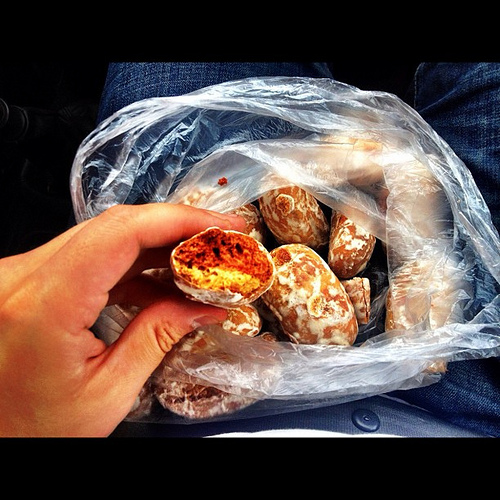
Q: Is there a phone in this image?
A: No, there are no phones.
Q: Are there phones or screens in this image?
A: No, there are no phones or screens.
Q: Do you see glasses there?
A: No, there are no glasses.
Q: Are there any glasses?
A: No, there are no glasses.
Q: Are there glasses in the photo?
A: No, there are no glasses.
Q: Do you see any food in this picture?
A: Yes, there is food.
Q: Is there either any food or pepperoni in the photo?
A: Yes, there is food.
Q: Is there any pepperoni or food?
A: Yes, there is food.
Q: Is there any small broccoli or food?
A: Yes, there is small food.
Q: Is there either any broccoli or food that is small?
A: Yes, the food is small.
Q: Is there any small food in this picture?
A: Yes, there is small food.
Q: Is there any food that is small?
A: Yes, there is food that is small.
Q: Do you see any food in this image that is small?
A: Yes, there is food that is small.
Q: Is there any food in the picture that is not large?
A: Yes, there is small food.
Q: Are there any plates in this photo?
A: No, there are no plates.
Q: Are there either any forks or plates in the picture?
A: No, there are no plates or forks.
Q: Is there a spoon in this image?
A: No, there are no spoons.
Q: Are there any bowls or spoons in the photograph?
A: No, there are no spoons or bowls.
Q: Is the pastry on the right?
A: Yes, the pastry is on the right of the image.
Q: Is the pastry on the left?
A: No, the pastry is on the right of the image.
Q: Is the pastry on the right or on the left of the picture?
A: The pastry is on the right of the image.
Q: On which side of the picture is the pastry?
A: The pastry is on the right of the image.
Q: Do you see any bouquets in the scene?
A: No, there are no bouquets.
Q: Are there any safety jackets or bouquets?
A: No, there are no bouquets or safety jackets.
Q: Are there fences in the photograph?
A: No, there are no fences.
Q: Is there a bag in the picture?
A: Yes, there is a bag.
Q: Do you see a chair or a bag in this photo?
A: Yes, there is a bag.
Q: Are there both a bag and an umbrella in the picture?
A: No, there is a bag but no umbrellas.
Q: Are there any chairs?
A: No, there are no chairs.